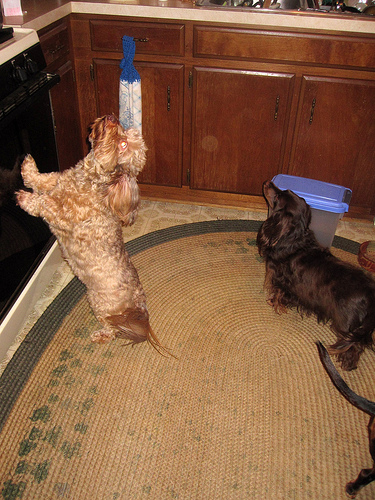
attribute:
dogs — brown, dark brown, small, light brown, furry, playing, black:
[16, 119, 374, 390]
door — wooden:
[188, 63, 290, 183]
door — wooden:
[100, 67, 190, 187]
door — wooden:
[284, 72, 363, 196]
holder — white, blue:
[120, 54, 145, 166]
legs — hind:
[93, 310, 116, 342]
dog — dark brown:
[255, 184, 359, 357]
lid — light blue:
[268, 171, 351, 209]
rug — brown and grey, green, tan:
[1, 218, 363, 490]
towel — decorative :
[118, 34, 141, 132]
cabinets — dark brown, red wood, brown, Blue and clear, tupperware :
[39, 2, 360, 219]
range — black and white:
[1, 27, 66, 324]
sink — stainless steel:
[194, 0, 363, 17]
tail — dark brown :
[106, 305, 172, 358]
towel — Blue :
[116, 33, 141, 129]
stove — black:
[1, 24, 58, 324]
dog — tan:
[17, 111, 149, 344]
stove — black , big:
[1, 24, 67, 326]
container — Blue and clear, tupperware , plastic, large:
[269, 173, 352, 250]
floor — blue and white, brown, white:
[1, 193, 361, 496]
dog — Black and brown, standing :
[256, 180, 360, 370]